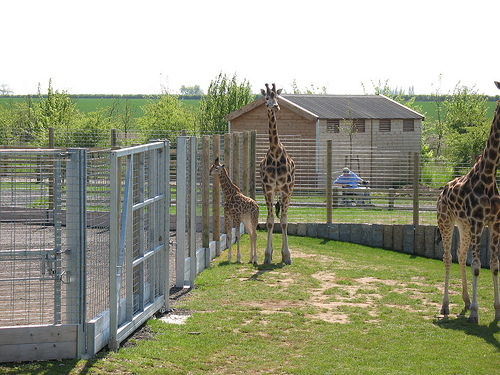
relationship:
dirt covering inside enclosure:
[0, 176, 488, 373] [1, 130, 498, 372]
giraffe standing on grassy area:
[434, 78, 498, 330] [0, 230, 498, 372]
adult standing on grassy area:
[258, 81, 298, 267] [0, 230, 498, 372]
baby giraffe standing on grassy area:
[206, 156, 259, 262] [0, 230, 498, 372]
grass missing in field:
[288, 193, 436, 228] [2, 95, 492, 367]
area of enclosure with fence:
[0, 128, 225, 327] [1, 136, 248, 360]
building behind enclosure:
[206, 86, 437, 208] [1, 130, 498, 372]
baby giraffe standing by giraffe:
[206, 156, 259, 262] [257, 81, 297, 268]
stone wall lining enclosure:
[341, 221, 426, 248] [1, 130, 498, 372]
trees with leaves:
[3, 73, 491, 190] [3, 73, 490, 184]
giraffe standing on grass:
[434, 78, 498, 330] [251, 249, 431, 353]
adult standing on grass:
[258, 81, 298, 267] [251, 249, 431, 353]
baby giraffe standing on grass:
[206, 156, 259, 262] [251, 249, 431, 353]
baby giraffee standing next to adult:
[208, 156, 257, 263] [258, 81, 298, 267]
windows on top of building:
[320, 115, 422, 135] [222, 93, 423, 196]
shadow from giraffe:
[426, 300, 499, 360] [417, 78, 499, 335]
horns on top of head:
[260, 77, 275, 92] [257, 82, 280, 114]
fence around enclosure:
[39, 113, 243, 322] [130, 104, 455, 364]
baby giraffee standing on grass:
[208, 156, 257, 263] [305, 288, 405, 345]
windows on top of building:
[319, 109, 406, 151] [222, 93, 423, 196]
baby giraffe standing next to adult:
[204, 159, 259, 262] [258, 81, 298, 267]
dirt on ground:
[323, 295, 383, 323] [266, 264, 391, 345]